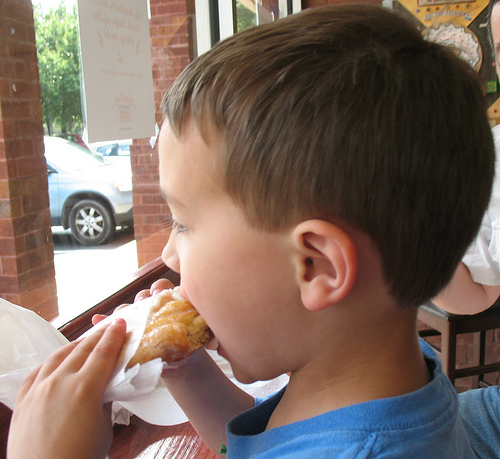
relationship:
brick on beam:
[9, 79, 34, 102] [1, 0, 61, 323]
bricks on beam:
[10, 192, 44, 253] [1, 5, 63, 328]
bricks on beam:
[0, 157, 57, 189] [0, 7, 61, 353]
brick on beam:
[0, 100, 30, 119] [2, 0, 58, 320]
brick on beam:
[132, 203, 162, 214] [126, 2, 200, 276]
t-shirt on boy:
[251, 392, 448, 456] [143, 112, 465, 424]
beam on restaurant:
[1, 0, 61, 323] [0, 0, 500, 459]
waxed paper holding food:
[2, 286, 185, 413] [124, 284, 214, 374]